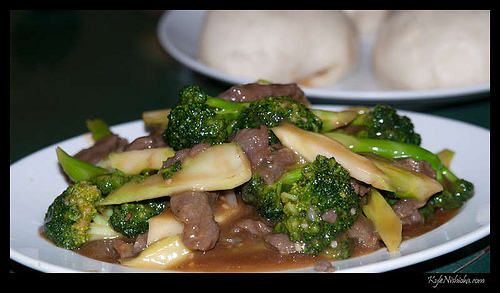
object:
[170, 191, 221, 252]
beef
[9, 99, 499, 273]
plate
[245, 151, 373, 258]
broccoli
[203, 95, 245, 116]
stem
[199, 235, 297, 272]
sauce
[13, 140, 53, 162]
edge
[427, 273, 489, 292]
graphic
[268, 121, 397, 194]
bamboo shoot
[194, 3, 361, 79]
dough ball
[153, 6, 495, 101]
plate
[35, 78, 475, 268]
food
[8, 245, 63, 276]
reflection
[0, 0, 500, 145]
table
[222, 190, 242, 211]
onion